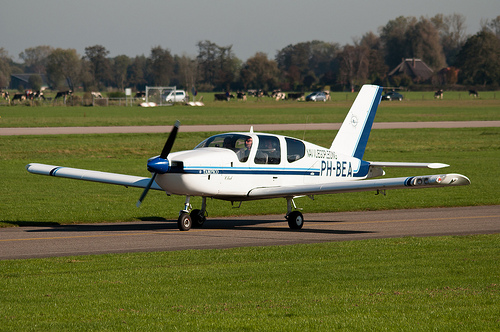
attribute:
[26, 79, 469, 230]
plane — white, blue and white, blue, striped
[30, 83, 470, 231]
airplane — white, blue and white, small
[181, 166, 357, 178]
stripes — blue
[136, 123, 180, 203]
prop — blue airplane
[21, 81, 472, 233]
aircraft — small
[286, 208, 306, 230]
tire — black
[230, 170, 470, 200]
wing — white, airplane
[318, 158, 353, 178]
letters — black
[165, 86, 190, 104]
van — gray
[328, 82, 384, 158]
tail — white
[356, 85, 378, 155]
stripe — blue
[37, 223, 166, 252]
asphalt — gray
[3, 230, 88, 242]
stripe — yellow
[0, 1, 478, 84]
sky — daytime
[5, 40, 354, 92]
trees — line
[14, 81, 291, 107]
animals — farm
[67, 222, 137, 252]
surface — paved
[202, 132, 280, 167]
cockpit — plane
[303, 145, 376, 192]
letters — on side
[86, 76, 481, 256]
plane — white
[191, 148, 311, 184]
stripes — blue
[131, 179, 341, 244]
gear — landing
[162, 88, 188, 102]
van — small, gray, mini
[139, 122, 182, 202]
propeller — blue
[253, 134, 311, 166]
windows — side